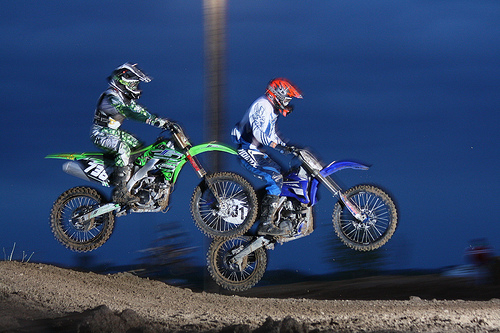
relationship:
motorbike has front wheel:
[206, 144, 400, 293] [330, 181, 400, 254]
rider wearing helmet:
[228, 78, 303, 238] [265, 76, 304, 118]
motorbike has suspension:
[206, 144, 400, 293] [313, 168, 366, 224]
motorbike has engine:
[206, 144, 400, 293] [269, 197, 312, 247]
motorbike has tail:
[44, 119, 258, 253] [60, 161, 88, 181]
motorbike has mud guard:
[206, 144, 400, 293] [308, 159, 372, 209]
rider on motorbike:
[228, 78, 303, 238] [206, 144, 400, 293]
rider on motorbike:
[89, 61, 180, 204] [44, 119, 258, 253]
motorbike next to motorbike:
[206, 144, 400, 293] [44, 119, 258, 253]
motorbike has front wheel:
[44, 119, 258, 253] [189, 169, 259, 242]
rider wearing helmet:
[89, 61, 180, 204] [103, 62, 152, 101]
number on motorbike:
[217, 199, 249, 225] [206, 144, 400, 293]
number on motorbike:
[82, 157, 115, 183] [44, 119, 258, 253]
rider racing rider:
[228, 78, 303, 238] [89, 61, 180, 204]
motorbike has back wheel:
[206, 144, 400, 293] [205, 230, 266, 292]